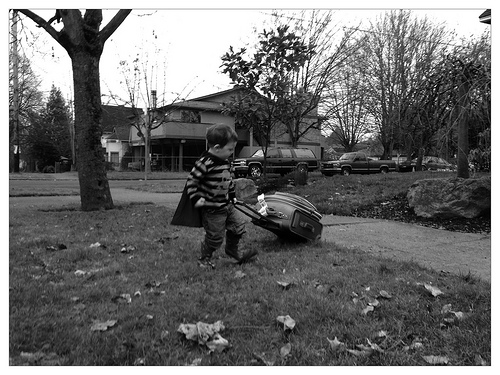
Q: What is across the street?
A: House.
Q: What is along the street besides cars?
A: Trees.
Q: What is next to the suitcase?
A: Sidewalk.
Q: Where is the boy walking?
A: In the yard.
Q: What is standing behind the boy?
A: Tree.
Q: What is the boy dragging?
A: A trolley.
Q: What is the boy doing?
A: Dragging a trolley.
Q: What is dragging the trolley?
A: A boy.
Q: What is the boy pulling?
A: Suitcase.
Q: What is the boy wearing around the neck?
A: Cape.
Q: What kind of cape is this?
A: Black material cape.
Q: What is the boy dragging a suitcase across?
A: Green grass.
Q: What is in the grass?
A: Leaves.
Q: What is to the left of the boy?
A: Tree.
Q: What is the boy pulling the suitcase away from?
A: Driveway.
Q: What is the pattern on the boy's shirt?
A: Stripes.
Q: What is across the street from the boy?
A: House.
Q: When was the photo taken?
A: Day time.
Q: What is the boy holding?
A: A suitcase.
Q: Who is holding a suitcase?
A: The boy.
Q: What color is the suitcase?
A: Black.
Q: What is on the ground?
A: Leaves.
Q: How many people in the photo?
A: One.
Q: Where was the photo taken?
A: In a yard.